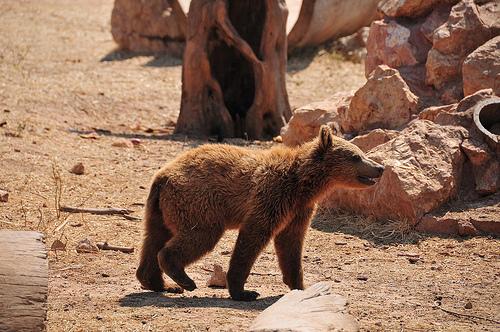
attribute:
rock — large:
[309, 112, 464, 221]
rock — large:
[273, 60, 416, 146]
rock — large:
[462, 33, 499, 103]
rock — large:
[365, 17, 422, 70]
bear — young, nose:
[365, 156, 391, 179]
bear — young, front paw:
[123, 124, 379, 298]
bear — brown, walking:
[125, 117, 399, 294]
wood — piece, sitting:
[248, 287, 353, 325]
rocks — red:
[351, 110, 468, 218]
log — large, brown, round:
[2, 228, 52, 330]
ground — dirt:
[2, 4, 492, 328]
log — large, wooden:
[2, 224, 60, 331]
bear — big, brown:
[135, 109, 385, 287]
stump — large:
[168, 0, 294, 146]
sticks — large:
[0, 2, 180, 329]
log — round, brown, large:
[243, 276, 357, 329]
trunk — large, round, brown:
[170, 0, 297, 144]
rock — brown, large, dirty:
[271, 60, 470, 230]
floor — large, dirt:
[0, 0, 498, 330]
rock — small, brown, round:
[66, 158, 94, 178]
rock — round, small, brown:
[50, 234, 69, 248]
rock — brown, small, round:
[0, 117, 10, 127]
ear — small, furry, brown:
[316, 120, 335, 150]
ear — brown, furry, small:
[322, 118, 341, 138]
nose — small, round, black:
[368, 159, 388, 182]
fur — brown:
[191, 152, 257, 196]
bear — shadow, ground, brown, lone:
[139, 124, 392, 304]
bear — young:
[137, 107, 381, 318]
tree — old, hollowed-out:
[171, 50, 286, 123]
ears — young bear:
[314, 122, 341, 153]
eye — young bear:
[338, 146, 357, 164]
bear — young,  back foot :
[230, 282, 264, 312]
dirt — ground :
[51, 58, 116, 140]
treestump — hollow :
[155, 1, 305, 142]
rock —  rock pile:
[344, 21, 474, 177]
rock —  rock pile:
[370, 12, 475, 94]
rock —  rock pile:
[372, 12, 475, 151]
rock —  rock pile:
[389, 1, 479, 124]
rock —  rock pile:
[345, 13, 477, 160]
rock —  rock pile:
[384, 10, 466, 129]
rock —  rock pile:
[396, 15, 483, 123]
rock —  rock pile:
[394, 70, 469, 205]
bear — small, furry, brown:
[119, 113, 389, 305]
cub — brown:
[122, 114, 388, 304]